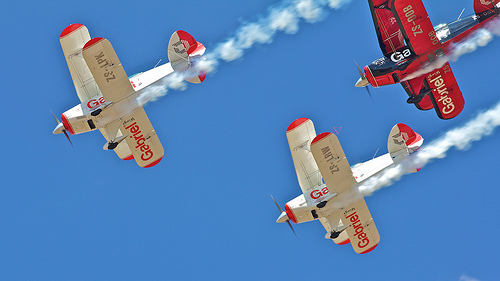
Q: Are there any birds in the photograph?
A: No, there are no birds.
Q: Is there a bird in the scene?
A: No, there are no birds.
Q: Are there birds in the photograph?
A: No, there are no birds.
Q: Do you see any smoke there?
A: Yes, there is smoke.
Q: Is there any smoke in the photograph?
A: Yes, there is smoke.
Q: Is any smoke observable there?
A: Yes, there is smoke.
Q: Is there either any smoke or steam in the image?
A: Yes, there is smoke.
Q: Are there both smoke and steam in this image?
A: No, there is smoke but no steam.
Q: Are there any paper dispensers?
A: No, there are no paper dispensers.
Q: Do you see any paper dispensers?
A: No, there are no paper dispensers.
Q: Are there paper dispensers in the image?
A: No, there are no paper dispensers.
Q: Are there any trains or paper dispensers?
A: No, there are no paper dispensers or trains.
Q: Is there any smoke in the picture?
A: Yes, there is smoke.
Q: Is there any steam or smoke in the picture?
A: Yes, there is smoke.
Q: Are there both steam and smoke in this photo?
A: No, there is smoke but no steam.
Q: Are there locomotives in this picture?
A: No, there are no locomotives.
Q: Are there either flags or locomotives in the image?
A: No, there are no locomotives or flags.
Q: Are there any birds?
A: No, there are no birds.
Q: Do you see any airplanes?
A: Yes, there is an airplane.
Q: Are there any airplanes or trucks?
A: Yes, there is an airplane.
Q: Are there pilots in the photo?
A: No, there are no pilots.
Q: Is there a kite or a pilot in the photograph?
A: No, there are no pilots or kites.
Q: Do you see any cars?
A: No, there are no cars.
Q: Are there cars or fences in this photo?
A: No, there are no cars or fences.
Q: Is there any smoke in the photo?
A: Yes, there is smoke.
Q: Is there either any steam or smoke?
A: Yes, there is smoke.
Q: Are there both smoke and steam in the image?
A: No, there is smoke but no steam.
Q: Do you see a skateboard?
A: No, there are no skateboards.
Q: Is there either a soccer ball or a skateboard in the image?
A: No, there are no skateboards or soccer balls.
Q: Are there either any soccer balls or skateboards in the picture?
A: No, there are no skateboards or soccer balls.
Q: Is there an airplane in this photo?
A: Yes, there is an airplane.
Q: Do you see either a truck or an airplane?
A: Yes, there is an airplane.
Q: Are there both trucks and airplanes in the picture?
A: No, there is an airplane but no trucks.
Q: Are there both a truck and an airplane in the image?
A: No, there is an airplane but no trucks.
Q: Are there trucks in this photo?
A: No, there are no trucks.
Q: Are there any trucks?
A: No, there are no trucks.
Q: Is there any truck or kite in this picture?
A: No, there are no trucks or kites.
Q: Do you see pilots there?
A: No, there are no pilots.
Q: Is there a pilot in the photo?
A: No, there are no pilots.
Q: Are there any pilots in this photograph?
A: No, there are no pilots.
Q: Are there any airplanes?
A: Yes, there is an airplane.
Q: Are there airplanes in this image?
A: Yes, there is an airplane.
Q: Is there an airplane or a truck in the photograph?
A: Yes, there is an airplane.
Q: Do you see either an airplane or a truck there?
A: Yes, there is an airplane.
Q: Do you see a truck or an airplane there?
A: Yes, there is an airplane.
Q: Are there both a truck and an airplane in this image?
A: No, there is an airplane but no trucks.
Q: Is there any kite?
A: No, there are no kites.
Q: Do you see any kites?
A: No, there are no kites.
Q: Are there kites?
A: No, there are no kites.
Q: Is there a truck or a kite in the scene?
A: No, there are no kites or trucks.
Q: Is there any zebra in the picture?
A: No, there are no zebras.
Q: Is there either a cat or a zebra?
A: No, there are no zebras or cats.